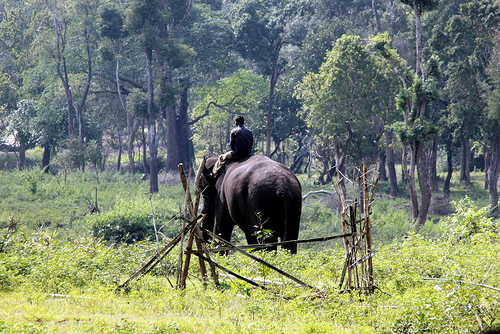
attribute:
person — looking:
[208, 110, 254, 164]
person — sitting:
[210, 115, 254, 177]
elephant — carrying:
[181, 149, 308, 264]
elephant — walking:
[193, 153, 303, 251]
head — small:
[233, 114, 245, 126]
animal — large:
[193, 148, 301, 247]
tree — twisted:
[418, 25, 455, 195]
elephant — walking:
[154, 153, 308, 244]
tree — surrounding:
[300, 37, 394, 215]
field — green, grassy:
[1, 165, 498, 332]